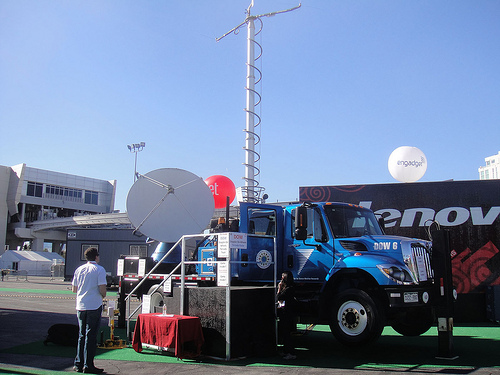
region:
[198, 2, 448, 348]
Truck with a huge satellite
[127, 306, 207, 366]
Table with red covering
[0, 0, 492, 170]
Crystal clear blue sky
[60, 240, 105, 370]
Man looking at satellites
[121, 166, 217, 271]
Large satellite dish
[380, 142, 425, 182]
Large white balloon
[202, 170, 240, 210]
Large red balloon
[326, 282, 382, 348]
Big semi tire with white rim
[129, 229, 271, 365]
Staircase to view the satellite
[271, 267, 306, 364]
Lady standing next to tall truck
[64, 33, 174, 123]
Sky is blue color.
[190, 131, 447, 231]
Two balloons are flying.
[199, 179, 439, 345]
Truck is blue color.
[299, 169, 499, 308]
Board is black color.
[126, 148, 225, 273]
Dish is white color.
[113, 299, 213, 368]
Table cloth is red color.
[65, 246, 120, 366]
Man is standing in the ground.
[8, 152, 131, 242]
Building is white color.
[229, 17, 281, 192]
Pole is grey color.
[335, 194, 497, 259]
Letters are white color.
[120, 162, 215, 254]
A satellite dish.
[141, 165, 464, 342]
A large blue truck.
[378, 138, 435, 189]
A large white balloon.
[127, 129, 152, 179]
a tall stadium light.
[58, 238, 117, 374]
A man standing near a truck.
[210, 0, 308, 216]
A tall antennae on a truck.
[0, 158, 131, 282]
A tall white building.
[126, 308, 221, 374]
A table with a red cloth.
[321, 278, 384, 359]
The right front tire of a car.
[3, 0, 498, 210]
A clear blue sky.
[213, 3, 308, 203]
Antenna sticking up from truck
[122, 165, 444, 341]
Blue work vehicle with satellite dish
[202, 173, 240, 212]
Balloon with Cnet logo on it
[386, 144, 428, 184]
White balloon with advertisement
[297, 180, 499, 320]
Big advertisement behind the truck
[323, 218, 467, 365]
Front wheels of truck are lifted off the ground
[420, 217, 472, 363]
Jack being used to lift the truck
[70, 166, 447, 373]
Man looking at the truck and satellite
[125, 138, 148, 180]
Tall lights in the distance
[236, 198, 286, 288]
Truck door is open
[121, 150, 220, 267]
radar dish on truck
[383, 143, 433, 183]
white ball on top of sign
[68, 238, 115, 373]
mad looking at dish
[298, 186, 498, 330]
lenovo advertisement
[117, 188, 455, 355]
big blue truck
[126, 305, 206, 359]
table with red cloth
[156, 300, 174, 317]
water bottle on table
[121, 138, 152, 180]
four lights on pole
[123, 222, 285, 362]
portable staircase next to truck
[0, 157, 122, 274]
white building in the background